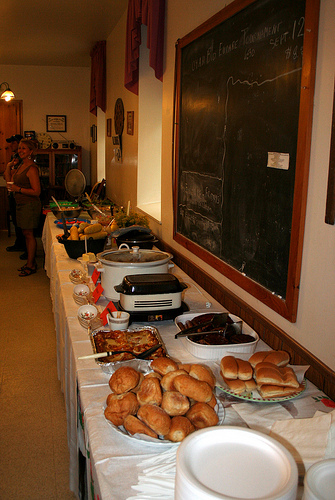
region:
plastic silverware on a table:
[134, 455, 171, 497]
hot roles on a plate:
[214, 348, 299, 401]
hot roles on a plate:
[103, 366, 184, 436]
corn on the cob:
[66, 221, 98, 244]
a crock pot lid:
[97, 245, 179, 269]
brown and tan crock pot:
[114, 275, 190, 317]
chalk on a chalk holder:
[267, 283, 289, 304]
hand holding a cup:
[3, 174, 24, 202]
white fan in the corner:
[60, 164, 89, 199]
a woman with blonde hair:
[13, 133, 34, 165]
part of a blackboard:
[220, 136, 258, 197]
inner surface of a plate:
[223, 456, 257, 485]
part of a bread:
[255, 368, 275, 383]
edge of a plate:
[182, 472, 200, 487]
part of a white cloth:
[121, 456, 149, 477]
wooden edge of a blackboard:
[209, 255, 237, 283]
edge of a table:
[88, 454, 103, 487]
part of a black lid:
[129, 277, 163, 290]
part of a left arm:
[9, 184, 31, 197]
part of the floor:
[2, 406, 36, 461]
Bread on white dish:
[100, 347, 230, 447]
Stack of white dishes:
[156, 422, 303, 498]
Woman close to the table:
[2, 134, 46, 283]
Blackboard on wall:
[150, 19, 322, 319]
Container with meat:
[171, 301, 268, 356]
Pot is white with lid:
[87, 239, 177, 301]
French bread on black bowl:
[54, 216, 110, 262]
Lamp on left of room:
[0, 75, 16, 101]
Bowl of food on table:
[45, 196, 83, 222]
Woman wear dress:
[4, 132, 47, 287]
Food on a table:
[39, 206, 234, 453]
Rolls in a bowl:
[83, 356, 228, 444]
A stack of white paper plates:
[156, 420, 310, 490]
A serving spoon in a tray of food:
[75, 342, 170, 364]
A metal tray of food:
[80, 325, 166, 366]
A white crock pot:
[86, 243, 179, 297]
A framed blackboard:
[153, 32, 307, 342]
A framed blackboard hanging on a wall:
[166, 25, 322, 336]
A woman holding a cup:
[3, 132, 43, 288]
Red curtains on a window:
[67, 25, 114, 171]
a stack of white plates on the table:
[158, 418, 293, 497]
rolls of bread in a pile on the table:
[103, 353, 230, 442]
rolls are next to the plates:
[110, 355, 228, 441]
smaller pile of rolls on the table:
[206, 339, 332, 411]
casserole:
[76, 314, 175, 370]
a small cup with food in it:
[102, 303, 133, 330]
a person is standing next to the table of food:
[0, 132, 62, 281]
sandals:
[16, 252, 43, 285]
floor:
[4, 280, 97, 496]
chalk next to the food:
[235, 262, 293, 308]